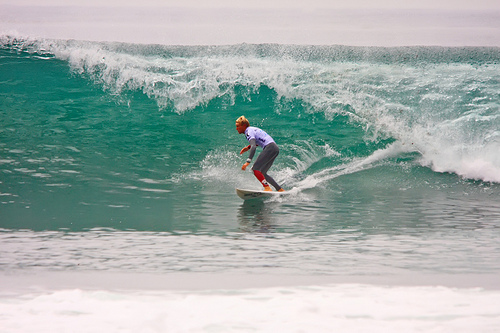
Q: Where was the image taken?
A: It was taken at the ocean.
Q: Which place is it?
A: It is an ocean.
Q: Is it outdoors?
A: Yes, it is outdoors.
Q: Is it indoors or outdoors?
A: It is outdoors.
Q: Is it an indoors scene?
A: No, it is outdoors.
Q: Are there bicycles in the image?
A: No, there are no bicycles.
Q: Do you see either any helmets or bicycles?
A: No, there are no bicycles or helmets.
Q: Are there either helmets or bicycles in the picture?
A: No, there are no bicycles or helmets.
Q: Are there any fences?
A: No, there are no fences.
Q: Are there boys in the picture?
A: No, there are no boys.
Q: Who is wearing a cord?
A: The man is wearing a cord.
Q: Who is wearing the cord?
A: The man is wearing a cord.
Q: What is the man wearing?
A: The man is wearing a wire.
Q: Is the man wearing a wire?
A: Yes, the man is wearing a wire.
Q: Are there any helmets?
A: No, there are no helmets.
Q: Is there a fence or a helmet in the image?
A: No, there are no helmets or fences.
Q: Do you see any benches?
A: No, there are no benches.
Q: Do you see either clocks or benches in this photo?
A: No, there are no benches or clocks.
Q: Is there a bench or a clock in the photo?
A: No, there are no benches or clocks.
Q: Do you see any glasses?
A: No, there are no glasses.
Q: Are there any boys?
A: No, there are no boys.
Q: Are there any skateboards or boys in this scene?
A: No, there are no boys or skateboards.